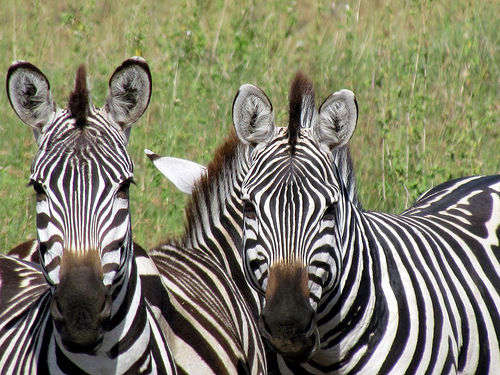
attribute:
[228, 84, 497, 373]
zebra — white, black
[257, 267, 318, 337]
nose — black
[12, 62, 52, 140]
ear — black outlined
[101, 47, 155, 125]
ear — black outlined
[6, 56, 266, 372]
zebra — black, white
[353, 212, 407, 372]
stripe — black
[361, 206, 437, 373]
stripe — black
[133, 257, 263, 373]
stripe — black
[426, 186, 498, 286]
stripe — black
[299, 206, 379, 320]
stripe — black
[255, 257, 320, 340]
nose — brown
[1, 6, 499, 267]
grass — tall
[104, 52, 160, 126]
ear — round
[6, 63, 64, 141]
ear — round